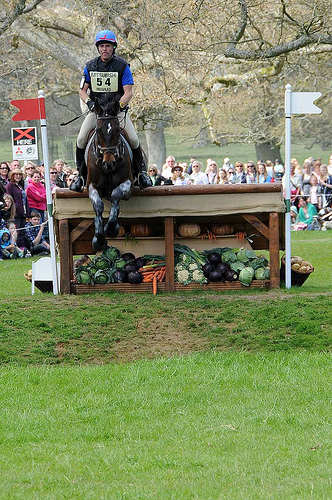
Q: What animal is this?
A: Horse.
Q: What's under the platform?
A: Vegetables.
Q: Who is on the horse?
A: Jockey.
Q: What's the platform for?
A: Hurdle.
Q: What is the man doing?
A: Jumping a horse.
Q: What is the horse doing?
A: Jumping a fence.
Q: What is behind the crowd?
A: Trees.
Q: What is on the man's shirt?
A: A bib with the number 54.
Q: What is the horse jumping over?
A: A vegetable stand.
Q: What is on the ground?
A: Green grass.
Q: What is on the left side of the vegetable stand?
A: A red flag.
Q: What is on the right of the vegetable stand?
A: A white flag.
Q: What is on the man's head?
A: A blue helmet.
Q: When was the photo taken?
A: During the day.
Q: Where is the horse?
A: Jumping over the fence.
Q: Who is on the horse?
A: THe man.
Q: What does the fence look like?
A: A counter with food.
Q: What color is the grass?
A: Green.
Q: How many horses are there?
A: One.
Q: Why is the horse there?
A: It is a race.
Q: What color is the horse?
A: Black.